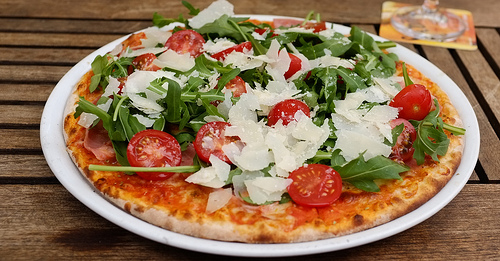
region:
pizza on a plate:
[58, 39, 435, 259]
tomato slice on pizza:
[272, 142, 341, 237]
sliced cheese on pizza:
[319, 87, 397, 153]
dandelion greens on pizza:
[341, 146, 414, 201]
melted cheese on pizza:
[99, 188, 180, 213]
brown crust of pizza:
[360, 150, 457, 235]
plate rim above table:
[425, 121, 487, 233]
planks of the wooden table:
[5, 20, 55, 107]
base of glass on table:
[385, 12, 480, 44]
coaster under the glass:
[442, 11, 484, 61]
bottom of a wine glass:
[377, 4, 492, 70]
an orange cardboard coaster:
[380, 2, 483, 54]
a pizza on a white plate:
[31, 7, 495, 259]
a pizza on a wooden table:
[22, 6, 490, 255]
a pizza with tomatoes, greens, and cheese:
[33, 5, 475, 250]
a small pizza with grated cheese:
[35, 11, 497, 244]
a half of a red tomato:
[129, 123, 189, 183]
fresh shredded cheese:
[232, 119, 303, 168]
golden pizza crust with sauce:
[117, 188, 466, 255]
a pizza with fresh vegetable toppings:
[33, 10, 489, 239]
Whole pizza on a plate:
[39, 13, 479, 253]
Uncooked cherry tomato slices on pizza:
[293, 164, 336, 203]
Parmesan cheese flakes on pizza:
[241, 135, 283, 199]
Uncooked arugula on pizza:
[171, 87, 198, 120]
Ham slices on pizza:
[83, 128, 112, 153]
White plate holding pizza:
[41, 102, 83, 169]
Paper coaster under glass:
[381, 2, 479, 50]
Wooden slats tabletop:
[8, 5, 39, 116]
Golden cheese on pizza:
[162, 190, 202, 212]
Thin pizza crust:
[148, 206, 229, 241]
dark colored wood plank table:
[33, 19, 74, 53]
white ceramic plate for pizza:
[50, 44, 431, 249]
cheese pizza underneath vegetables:
[133, 180, 249, 257]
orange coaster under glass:
[392, 1, 480, 46]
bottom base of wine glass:
[402, 13, 471, 47]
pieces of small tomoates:
[285, 153, 346, 217]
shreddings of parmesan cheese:
[172, 71, 324, 195]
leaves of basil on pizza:
[135, 61, 372, 187]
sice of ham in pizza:
[75, 131, 130, 171]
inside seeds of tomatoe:
[145, 142, 166, 162]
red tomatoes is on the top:
[120, 137, 175, 163]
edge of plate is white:
[400, 210, 415, 220]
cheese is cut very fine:
[335, 100, 365, 140]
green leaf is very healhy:
[350, 160, 390, 175]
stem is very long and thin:
[90, 160, 170, 165]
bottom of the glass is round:
[410, 15, 430, 30]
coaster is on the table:
[460, 30, 465, 40]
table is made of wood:
[15, 35, 40, 65]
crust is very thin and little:
[65, 125, 75, 165]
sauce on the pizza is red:
[130, 182, 161, 192]